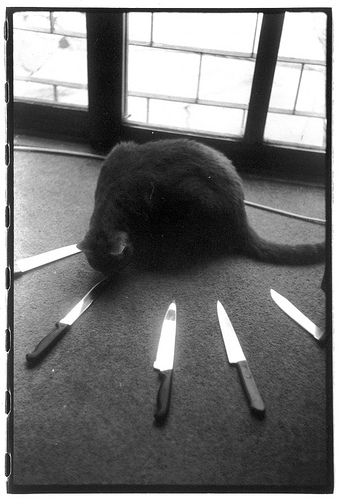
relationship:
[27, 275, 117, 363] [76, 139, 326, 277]
knife pointing at cat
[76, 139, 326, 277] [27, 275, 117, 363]
cat smelling knife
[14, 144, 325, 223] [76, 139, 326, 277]
cord behind cat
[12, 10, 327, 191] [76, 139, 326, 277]
window behind cat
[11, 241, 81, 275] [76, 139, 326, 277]
knife pointing to cat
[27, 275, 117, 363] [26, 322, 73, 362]
knife has a handle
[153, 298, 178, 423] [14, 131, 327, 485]
knife on floor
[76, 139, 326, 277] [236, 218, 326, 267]
cat has a tail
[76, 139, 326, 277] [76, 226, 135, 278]
cat has a head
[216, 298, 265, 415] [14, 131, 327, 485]
knife on floor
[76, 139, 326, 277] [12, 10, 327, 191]
cat in front of window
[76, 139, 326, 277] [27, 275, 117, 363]
cat near a knife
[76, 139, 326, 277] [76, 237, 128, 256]
cat has ears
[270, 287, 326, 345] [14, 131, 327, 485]
knife on floor